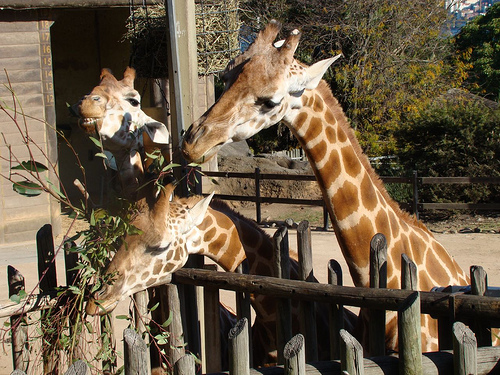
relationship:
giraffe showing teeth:
[69, 65, 174, 182] [77, 116, 103, 129]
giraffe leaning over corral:
[77, 184, 254, 329] [170, 215, 500, 374]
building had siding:
[2, 2, 221, 236] [2, 24, 38, 98]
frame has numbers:
[32, 12, 68, 209] [34, 11, 58, 108]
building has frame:
[2, 2, 221, 236] [159, 7, 197, 181]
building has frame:
[2, 2, 221, 236] [32, 12, 68, 209]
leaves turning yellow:
[333, 8, 484, 147] [427, 64, 438, 76]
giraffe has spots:
[173, 24, 332, 171] [300, 97, 384, 236]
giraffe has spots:
[77, 184, 254, 329] [194, 218, 243, 262]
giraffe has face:
[173, 24, 332, 171] [207, 70, 280, 134]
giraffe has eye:
[173, 24, 332, 171] [257, 95, 282, 113]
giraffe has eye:
[69, 65, 174, 182] [126, 95, 139, 112]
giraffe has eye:
[77, 184, 254, 329] [145, 241, 172, 260]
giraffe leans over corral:
[77, 184, 254, 329] [170, 215, 500, 374]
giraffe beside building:
[69, 65, 174, 182] [2, 2, 221, 236]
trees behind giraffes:
[313, 3, 500, 158] [28, 17, 336, 323]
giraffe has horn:
[173, 24, 332, 171] [281, 28, 306, 56]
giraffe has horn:
[69, 65, 174, 182] [121, 64, 138, 90]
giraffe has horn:
[77, 184, 254, 329] [155, 185, 179, 212]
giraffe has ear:
[173, 24, 332, 171] [311, 51, 348, 87]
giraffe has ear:
[69, 65, 174, 182] [143, 114, 175, 149]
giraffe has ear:
[77, 184, 254, 329] [189, 190, 218, 229]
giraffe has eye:
[173, 24, 332, 171] [145, 241, 172, 260]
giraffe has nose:
[173, 24, 332, 171] [185, 123, 206, 145]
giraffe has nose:
[69, 65, 174, 182] [80, 95, 103, 107]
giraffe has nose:
[77, 184, 254, 329] [89, 280, 115, 298]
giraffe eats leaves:
[173, 24, 332, 171] [76, 213, 132, 280]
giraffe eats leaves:
[69, 65, 174, 182] [76, 213, 132, 280]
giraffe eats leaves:
[77, 184, 254, 329] [76, 213, 132, 280]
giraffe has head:
[173, 24, 332, 171] [213, 36, 328, 138]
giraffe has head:
[69, 65, 174, 182] [96, 85, 143, 150]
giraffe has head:
[77, 184, 254, 329] [122, 219, 191, 293]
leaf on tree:
[14, 180, 43, 203] [6, 99, 168, 374]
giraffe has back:
[173, 24, 332, 171] [333, 100, 417, 229]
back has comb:
[333, 100, 417, 229] [331, 96, 358, 150]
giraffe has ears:
[77, 184, 254, 329] [150, 187, 217, 223]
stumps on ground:
[433, 227, 498, 238] [448, 239, 500, 295]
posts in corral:
[246, 167, 270, 230] [224, 170, 500, 307]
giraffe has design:
[173, 24, 332, 171] [311, 140, 384, 248]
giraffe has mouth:
[69, 65, 174, 182] [82, 107, 101, 134]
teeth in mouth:
[77, 116, 103, 129] [82, 107, 101, 134]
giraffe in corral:
[173, 24, 332, 171] [170, 215, 500, 374]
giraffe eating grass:
[173, 24, 332, 171] [152, 151, 207, 194]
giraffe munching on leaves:
[173, 24, 332, 171] [76, 213, 132, 280]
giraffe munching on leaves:
[77, 184, 254, 329] [76, 213, 132, 280]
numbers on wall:
[34, 11, 58, 108] [2, 11, 61, 240]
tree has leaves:
[313, 3, 500, 158] [333, 8, 484, 147]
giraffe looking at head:
[173, 24, 332, 171] [122, 219, 191, 293]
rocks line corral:
[423, 219, 499, 251] [170, 215, 500, 374]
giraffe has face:
[69, 65, 174, 182] [90, 89, 142, 131]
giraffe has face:
[77, 184, 254, 329] [111, 233, 180, 294]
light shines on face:
[241, 80, 248, 83] [207, 70, 280, 134]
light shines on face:
[241, 80, 248, 83] [90, 89, 142, 131]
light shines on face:
[241, 80, 248, 83] [111, 233, 180, 294]